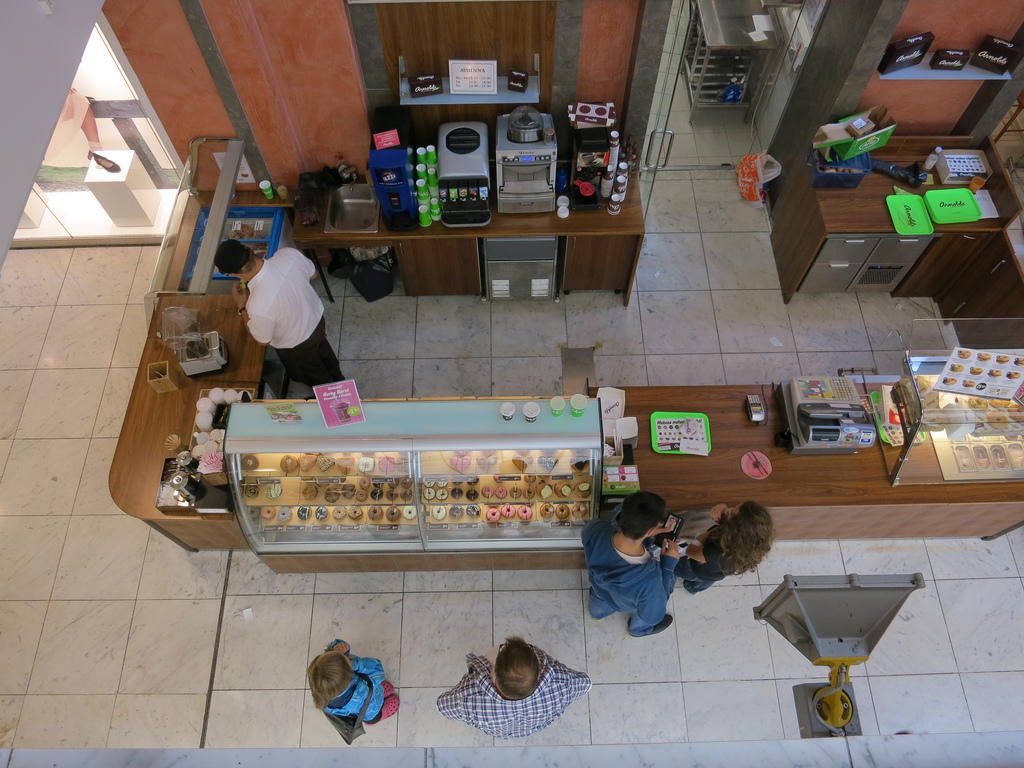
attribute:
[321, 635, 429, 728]
shirt — blue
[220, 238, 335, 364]
shirt — white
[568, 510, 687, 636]
jacket — blue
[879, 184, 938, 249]
tray — green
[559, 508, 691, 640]
sweater — blue